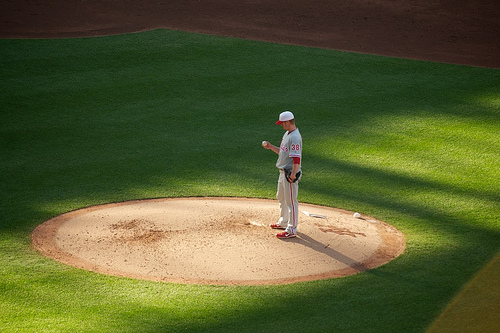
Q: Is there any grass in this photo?
A: Yes, there is grass.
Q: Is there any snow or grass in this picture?
A: Yes, there is grass.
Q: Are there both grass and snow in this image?
A: No, there is grass but no snow.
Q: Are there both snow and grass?
A: No, there is grass but no snow.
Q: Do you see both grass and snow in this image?
A: No, there is grass but no snow.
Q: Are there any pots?
A: No, there are no pots.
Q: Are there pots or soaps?
A: No, there are no pots or soaps.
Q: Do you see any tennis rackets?
A: No, there are no tennis rackets.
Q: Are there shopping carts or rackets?
A: No, there are no rackets or shopping carts.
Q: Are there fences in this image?
A: No, there are no fences.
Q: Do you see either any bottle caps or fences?
A: No, there are no fences or bottle caps.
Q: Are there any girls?
A: No, there are no girls.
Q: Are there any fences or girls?
A: No, there are no girls or fences.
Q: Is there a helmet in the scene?
A: No, there are no helmets.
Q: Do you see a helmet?
A: No, there are no helmets.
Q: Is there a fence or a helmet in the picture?
A: No, there are no helmets or fences.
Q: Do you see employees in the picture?
A: No, there are no employees.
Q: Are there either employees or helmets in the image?
A: No, there are no employees or helmets.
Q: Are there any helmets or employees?
A: No, there are no employees or helmets.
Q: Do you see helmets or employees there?
A: No, there are no employees or helmets.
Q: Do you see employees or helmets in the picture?
A: No, there are no employees or helmets.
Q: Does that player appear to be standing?
A: Yes, the player is standing.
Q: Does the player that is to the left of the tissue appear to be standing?
A: Yes, the player is standing.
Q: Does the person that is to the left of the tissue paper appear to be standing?
A: Yes, the player is standing.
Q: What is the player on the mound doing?
A: The player is standing.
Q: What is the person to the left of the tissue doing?
A: The player is standing.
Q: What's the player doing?
A: The player is standing.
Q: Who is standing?
A: The player is standing.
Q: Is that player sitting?
A: No, the player is standing.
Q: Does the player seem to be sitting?
A: No, the player is standing.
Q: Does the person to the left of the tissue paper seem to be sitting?
A: No, the player is standing.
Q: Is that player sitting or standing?
A: The player is standing.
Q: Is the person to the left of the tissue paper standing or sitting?
A: The player is standing.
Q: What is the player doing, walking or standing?
A: The player is standing.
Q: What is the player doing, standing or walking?
A: The player is standing.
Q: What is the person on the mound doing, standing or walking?
A: The player is standing.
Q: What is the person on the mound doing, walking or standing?
A: The player is standing.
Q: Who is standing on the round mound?
A: The player is standing on the mound.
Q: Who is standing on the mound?
A: The player is standing on the mound.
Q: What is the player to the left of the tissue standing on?
A: The player is standing on the mound.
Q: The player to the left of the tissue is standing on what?
A: The player is standing on the mound.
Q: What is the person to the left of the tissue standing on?
A: The player is standing on the mound.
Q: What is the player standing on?
A: The player is standing on the mound.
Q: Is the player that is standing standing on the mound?
A: Yes, the player is standing on the mound.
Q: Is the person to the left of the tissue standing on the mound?
A: Yes, the player is standing on the mound.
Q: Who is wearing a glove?
A: The player is wearing a glove.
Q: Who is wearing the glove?
A: The player is wearing a glove.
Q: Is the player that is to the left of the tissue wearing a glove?
A: Yes, the player is wearing a glove.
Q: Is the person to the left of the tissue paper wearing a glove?
A: Yes, the player is wearing a glove.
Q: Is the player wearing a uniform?
A: No, the player is wearing a glove.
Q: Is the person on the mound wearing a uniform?
A: No, the player is wearing a glove.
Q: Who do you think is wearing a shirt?
A: The player is wearing a shirt.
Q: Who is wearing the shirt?
A: The player is wearing a shirt.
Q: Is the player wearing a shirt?
A: Yes, the player is wearing a shirt.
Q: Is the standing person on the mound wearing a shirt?
A: Yes, the player is wearing a shirt.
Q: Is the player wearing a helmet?
A: No, the player is wearing a shirt.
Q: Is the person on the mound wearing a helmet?
A: No, the player is wearing a shirt.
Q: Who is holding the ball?
A: The player is holding the ball.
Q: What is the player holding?
A: The player is holding the ball.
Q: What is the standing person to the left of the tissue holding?
A: The player is holding the ball.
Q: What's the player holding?
A: The player is holding the ball.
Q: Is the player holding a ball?
A: Yes, the player is holding a ball.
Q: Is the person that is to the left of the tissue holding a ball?
A: Yes, the player is holding a ball.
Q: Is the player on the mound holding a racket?
A: No, the player is holding a ball.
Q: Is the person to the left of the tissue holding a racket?
A: No, the player is holding a ball.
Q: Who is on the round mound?
A: The player is on the mound.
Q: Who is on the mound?
A: The player is on the mound.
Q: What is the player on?
A: The player is on the mound.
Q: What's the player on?
A: The player is on the mound.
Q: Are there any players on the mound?
A: Yes, there is a player on the mound.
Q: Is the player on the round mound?
A: Yes, the player is on the mound.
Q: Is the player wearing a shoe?
A: Yes, the player is wearing a shoe.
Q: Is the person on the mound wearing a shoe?
A: Yes, the player is wearing a shoe.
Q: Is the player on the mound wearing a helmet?
A: No, the player is wearing a shoe.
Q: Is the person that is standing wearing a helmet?
A: No, the player is wearing a shoe.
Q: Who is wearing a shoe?
A: The player is wearing a shoe.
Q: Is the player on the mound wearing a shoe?
A: Yes, the player is wearing a shoe.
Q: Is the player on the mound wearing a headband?
A: No, the player is wearing a shoe.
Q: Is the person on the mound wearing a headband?
A: No, the player is wearing a shoe.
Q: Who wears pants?
A: The player wears pants.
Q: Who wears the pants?
A: The player wears pants.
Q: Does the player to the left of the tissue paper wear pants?
A: Yes, the player wears pants.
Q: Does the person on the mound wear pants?
A: Yes, the player wears pants.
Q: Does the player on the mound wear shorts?
A: No, the player wears pants.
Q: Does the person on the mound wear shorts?
A: No, the player wears pants.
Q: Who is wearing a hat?
A: The player is wearing a hat.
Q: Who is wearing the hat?
A: The player is wearing a hat.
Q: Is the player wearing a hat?
A: Yes, the player is wearing a hat.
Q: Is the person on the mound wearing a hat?
A: Yes, the player is wearing a hat.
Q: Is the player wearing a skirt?
A: No, the player is wearing a hat.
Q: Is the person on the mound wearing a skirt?
A: No, the player is wearing a hat.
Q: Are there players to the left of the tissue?
A: Yes, there is a player to the left of the tissue.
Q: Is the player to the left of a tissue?
A: Yes, the player is to the left of a tissue.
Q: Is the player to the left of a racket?
A: No, the player is to the left of a tissue.